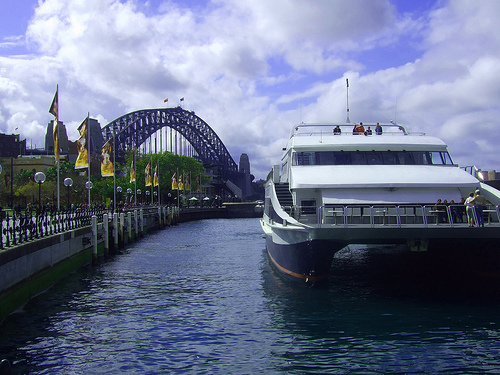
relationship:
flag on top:
[162, 95, 190, 108] [141, 112, 205, 132]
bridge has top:
[8, 106, 271, 227] [141, 112, 205, 132]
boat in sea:
[258, 121, 499, 291] [0, 209, 499, 375]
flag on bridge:
[74, 115, 89, 168] [0, 202, 182, 292]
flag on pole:
[127, 157, 136, 184] [128, 155, 138, 237]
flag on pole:
[150, 164, 159, 187] [155, 186, 160, 207]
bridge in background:
[98, 106, 239, 189] [66, 20, 257, 204]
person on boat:
[465, 189, 492, 228] [262, 116, 497, 299]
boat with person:
[262, 116, 497, 299] [465, 189, 492, 228]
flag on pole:
[47, 94, 62, 122] [37, 95, 69, 210]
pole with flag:
[37, 95, 69, 210] [47, 94, 62, 122]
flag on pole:
[141, 157, 152, 186] [154, 160, 163, 207]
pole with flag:
[154, 160, 163, 207] [141, 157, 152, 186]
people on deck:
[331, 120, 402, 145] [269, 114, 454, 153]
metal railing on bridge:
[0, 197, 207, 254] [80, 104, 242, 199]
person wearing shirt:
[466, 186, 494, 221] [467, 192, 489, 207]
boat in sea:
[258, 121, 499, 291] [16, 172, 495, 372]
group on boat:
[330, 120, 387, 141] [266, 101, 498, 288]